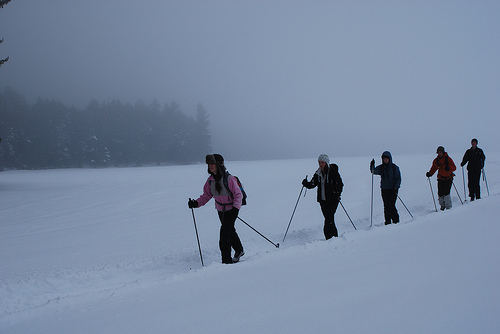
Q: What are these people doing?
A: Cross country skiing.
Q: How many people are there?
A: Five.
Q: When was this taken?
A: During the day.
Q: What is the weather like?
A: Snowy and cold.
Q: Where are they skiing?
A: Through the snow.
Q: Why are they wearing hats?
A: Its cold.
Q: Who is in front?
A: Person in pink coat.